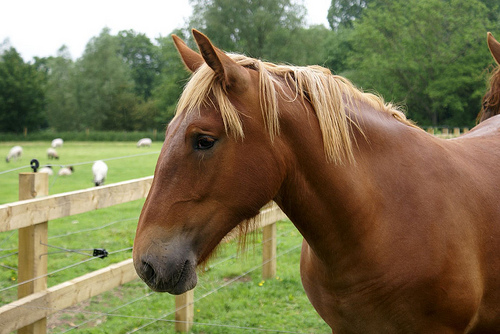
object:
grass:
[0, 141, 328, 334]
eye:
[192, 135, 218, 151]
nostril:
[139, 259, 159, 284]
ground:
[0, 140, 336, 334]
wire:
[0, 246, 133, 292]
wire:
[123, 242, 305, 334]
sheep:
[135, 135, 154, 148]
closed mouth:
[165, 257, 191, 296]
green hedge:
[0, 127, 164, 142]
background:
[0, 0, 500, 143]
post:
[14, 167, 52, 334]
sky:
[0, 0, 353, 65]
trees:
[0, 43, 51, 136]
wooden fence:
[0, 210, 274, 334]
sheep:
[89, 158, 110, 182]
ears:
[186, 24, 249, 90]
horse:
[125, 22, 500, 334]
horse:
[475, 28, 500, 122]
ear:
[170, 33, 207, 70]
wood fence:
[0, 176, 157, 233]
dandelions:
[258, 279, 266, 286]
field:
[0, 124, 500, 334]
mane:
[166, 44, 413, 166]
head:
[127, 23, 304, 297]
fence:
[0, 151, 296, 333]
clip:
[89, 245, 110, 260]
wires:
[59, 291, 156, 334]